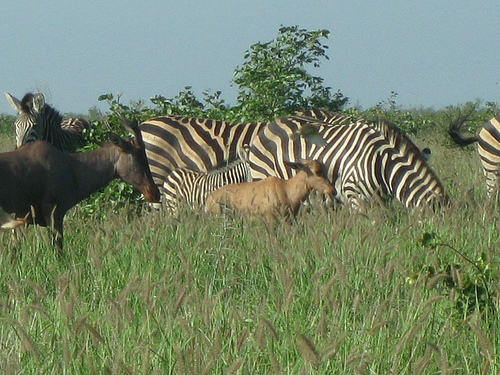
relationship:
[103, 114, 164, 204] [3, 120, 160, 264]
head of an animal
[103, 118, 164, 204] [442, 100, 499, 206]
head of an animal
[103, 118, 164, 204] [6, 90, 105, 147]
head of an animal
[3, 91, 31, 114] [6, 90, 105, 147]
ear of an animal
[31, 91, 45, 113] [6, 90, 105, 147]
ear of an animal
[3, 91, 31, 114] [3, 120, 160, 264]
ear of an animal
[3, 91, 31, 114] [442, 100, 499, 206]
ear of an animal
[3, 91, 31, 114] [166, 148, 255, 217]
ear of an animal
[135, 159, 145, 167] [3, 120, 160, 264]
eye of an animal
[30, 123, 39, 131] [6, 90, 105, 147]
eye of an animal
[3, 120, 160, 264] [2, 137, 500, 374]
animal in grass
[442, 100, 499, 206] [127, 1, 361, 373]
animal in middle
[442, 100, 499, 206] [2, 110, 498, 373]
animal in field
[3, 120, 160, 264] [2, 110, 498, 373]
animal in field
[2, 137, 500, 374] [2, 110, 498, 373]
grass in field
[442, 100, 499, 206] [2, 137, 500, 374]
animal in grass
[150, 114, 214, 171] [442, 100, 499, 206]
stripe of a animal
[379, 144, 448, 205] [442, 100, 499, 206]
neck of a animal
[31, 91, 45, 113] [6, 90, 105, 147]
ear of a zebra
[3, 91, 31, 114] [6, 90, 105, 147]
ear of a zebra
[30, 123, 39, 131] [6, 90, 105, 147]
eye of a zebra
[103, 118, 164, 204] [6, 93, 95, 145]
head of a zebra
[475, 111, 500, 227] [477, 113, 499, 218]
back of a zebra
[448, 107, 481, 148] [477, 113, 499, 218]
tail of a zebra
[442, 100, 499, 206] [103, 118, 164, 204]
animal has head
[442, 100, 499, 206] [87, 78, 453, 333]
animal of zebra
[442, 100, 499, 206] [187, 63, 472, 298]
animal of zebra